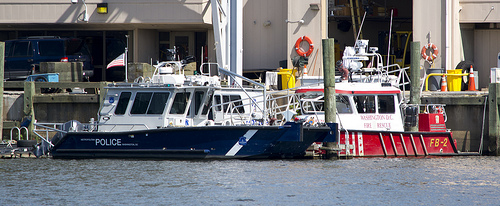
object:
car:
[26, 73, 60, 94]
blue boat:
[49, 38, 340, 160]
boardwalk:
[0, 82, 500, 152]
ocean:
[0, 157, 500, 206]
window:
[114, 91, 133, 115]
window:
[131, 91, 169, 116]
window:
[170, 90, 191, 115]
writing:
[81, 138, 138, 147]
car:
[0, 33, 126, 81]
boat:
[284, 38, 458, 157]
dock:
[0, 31, 500, 164]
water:
[0, 155, 498, 204]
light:
[96, 3, 108, 14]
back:
[96, 86, 172, 126]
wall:
[0, 0, 226, 24]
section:
[196, 167, 409, 202]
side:
[51, 85, 311, 160]